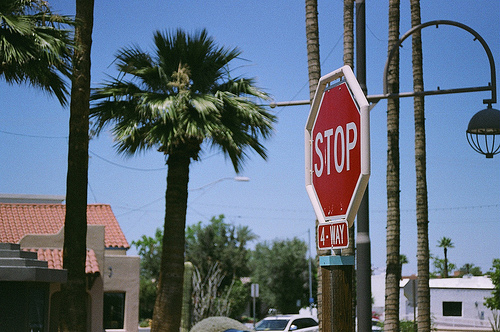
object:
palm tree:
[88, 25, 279, 331]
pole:
[249, 283, 258, 325]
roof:
[10, 245, 97, 271]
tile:
[90, 265, 102, 275]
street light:
[232, 175, 250, 183]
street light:
[463, 105, 498, 158]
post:
[317, 252, 357, 332]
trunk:
[149, 154, 192, 331]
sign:
[312, 221, 351, 252]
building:
[426, 274, 499, 332]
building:
[363, 274, 417, 321]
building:
[0, 196, 143, 331]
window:
[440, 300, 463, 316]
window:
[101, 290, 126, 329]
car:
[246, 313, 320, 331]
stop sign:
[303, 64, 371, 226]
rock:
[188, 314, 249, 331]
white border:
[302, 64, 373, 250]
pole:
[349, 0, 375, 331]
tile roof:
[0, 203, 132, 250]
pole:
[256, 86, 489, 112]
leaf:
[163, 26, 168, 46]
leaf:
[240, 79, 247, 95]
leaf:
[170, 95, 178, 120]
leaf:
[150, 99, 153, 122]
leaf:
[249, 137, 269, 153]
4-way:
[317, 223, 343, 248]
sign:
[249, 282, 259, 298]